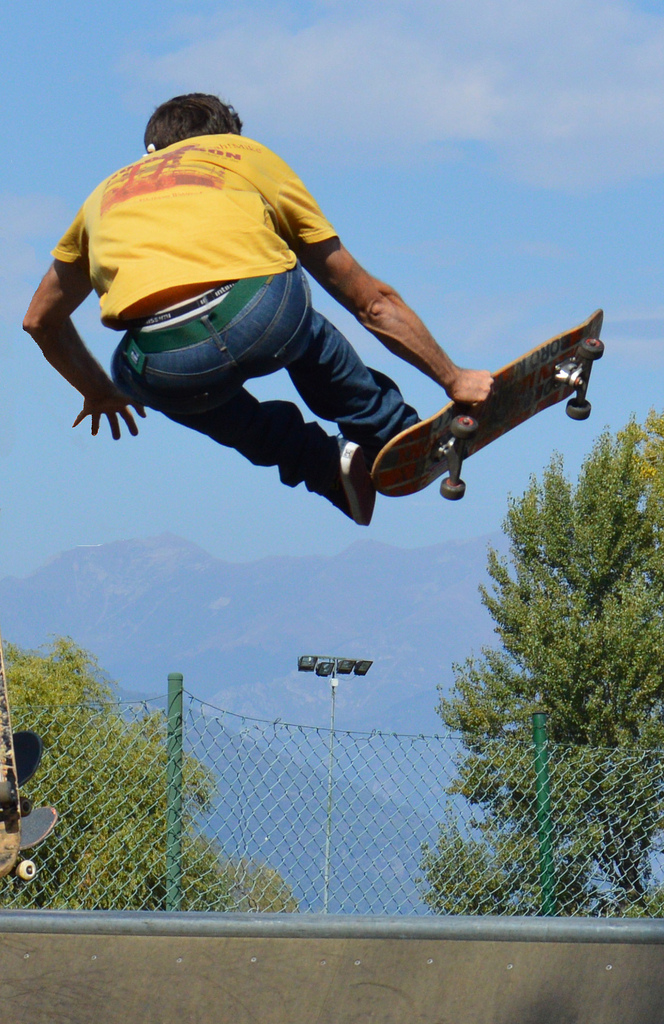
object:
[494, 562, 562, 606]
leaves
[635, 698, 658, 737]
leaves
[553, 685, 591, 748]
leaves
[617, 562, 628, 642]
leaves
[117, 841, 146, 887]
leaves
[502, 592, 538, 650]
leaves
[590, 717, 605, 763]
leaves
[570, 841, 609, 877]
leaves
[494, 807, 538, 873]
leaves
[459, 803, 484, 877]
leaves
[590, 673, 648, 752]
leaves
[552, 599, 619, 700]
leaves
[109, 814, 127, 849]
leaves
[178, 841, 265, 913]
leaves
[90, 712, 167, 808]
leaves